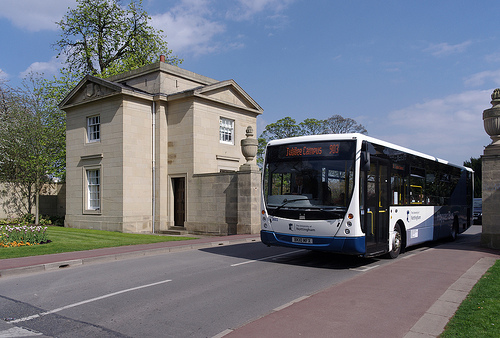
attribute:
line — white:
[7, 276, 175, 321]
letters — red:
[280, 138, 344, 160]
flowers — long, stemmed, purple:
[3, 225, 52, 245]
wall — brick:
[184, 162, 264, 243]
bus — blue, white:
[225, 129, 412, 239]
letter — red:
[282, 146, 292, 159]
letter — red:
[293, 146, 301, 156]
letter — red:
[299, 146, 307, 156]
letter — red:
[308, 147, 316, 156]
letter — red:
[313, 147, 323, 155]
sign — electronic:
[265, 135, 362, 158]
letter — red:
[294, 145, 306, 156]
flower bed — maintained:
[0, 221, 49, 246]